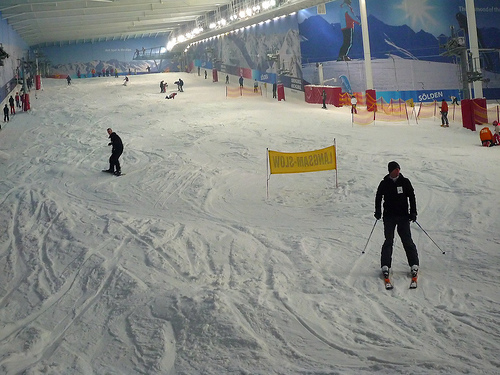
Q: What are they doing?
A: Skiing.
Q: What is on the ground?
A: Snow.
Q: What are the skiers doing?
A: Going downhill.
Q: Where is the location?
A: Ski park.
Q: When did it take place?
A: Winter.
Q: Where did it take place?
A: Ski slope.